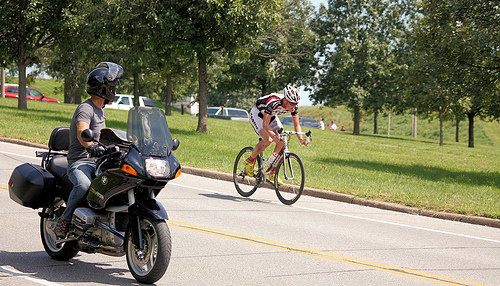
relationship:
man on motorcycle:
[61, 57, 126, 167] [44, 127, 166, 263]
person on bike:
[248, 86, 306, 138] [237, 150, 315, 199]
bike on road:
[237, 150, 315, 199] [237, 207, 393, 273]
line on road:
[239, 231, 306, 263] [237, 207, 393, 273]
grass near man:
[355, 144, 448, 209] [61, 57, 126, 167]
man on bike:
[61, 57, 126, 167] [237, 150, 315, 199]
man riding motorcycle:
[61, 57, 126, 167] [44, 127, 166, 263]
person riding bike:
[248, 86, 306, 138] [237, 150, 315, 199]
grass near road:
[355, 144, 448, 209] [237, 207, 393, 273]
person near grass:
[248, 86, 306, 138] [355, 144, 448, 209]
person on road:
[248, 86, 306, 138] [237, 207, 393, 273]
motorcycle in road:
[44, 127, 166, 263] [237, 207, 393, 273]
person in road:
[248, 86, 306, 138] [237, 207, 393, 273]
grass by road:
[355, 144, 448, 209] [237, 207, 393, 273]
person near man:
[248, 86, 306, 138] [61, 57, 126, 167]